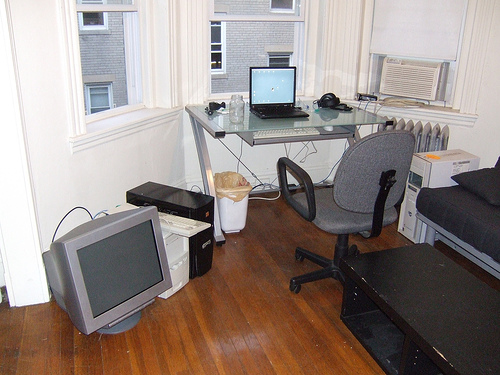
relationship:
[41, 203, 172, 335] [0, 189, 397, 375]
monitor sitting on floor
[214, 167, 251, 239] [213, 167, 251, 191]
garbage can with bag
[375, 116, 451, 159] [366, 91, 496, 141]
radiator attached to wall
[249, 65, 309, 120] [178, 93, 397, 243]
computer sitting on desk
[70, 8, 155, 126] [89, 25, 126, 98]
window with view of building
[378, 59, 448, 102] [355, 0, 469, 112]
air conditioner in window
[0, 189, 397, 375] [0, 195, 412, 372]
floor covered in dust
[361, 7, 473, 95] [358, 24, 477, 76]
blinds pulled closed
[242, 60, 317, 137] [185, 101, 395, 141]
computer on desk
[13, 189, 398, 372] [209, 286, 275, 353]
floor laid with wood paneling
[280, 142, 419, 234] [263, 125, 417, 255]
chair behind desk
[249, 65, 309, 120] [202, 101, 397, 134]
computer on table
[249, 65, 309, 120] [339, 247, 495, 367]
computer on table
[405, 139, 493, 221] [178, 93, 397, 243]
computer side of desk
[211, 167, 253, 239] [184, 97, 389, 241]
can under desk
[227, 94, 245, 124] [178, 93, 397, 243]
jar on desk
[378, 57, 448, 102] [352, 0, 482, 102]
air conditioner on window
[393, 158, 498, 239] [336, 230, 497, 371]
sofa next to box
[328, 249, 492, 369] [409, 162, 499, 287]
table in front of sofa